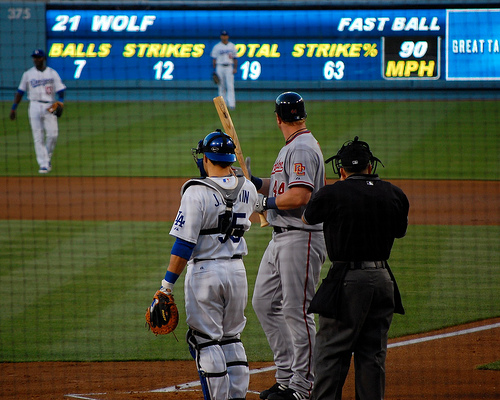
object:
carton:
[144, 278, 179, 336]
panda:
[45, 85, 53, 94]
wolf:
[90, 14, 156, 32]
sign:
[379, 36, 441, 81]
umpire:
[301, 135, 411, 400]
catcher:
[10, 48, 67, 174]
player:
[9, 48, 68, 174]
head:
[220, 30, 229, 42]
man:
[210, 29, 237, 109]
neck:
[221, 40, 229, 44]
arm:
[210, 44, 221, 78]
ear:
[220, 36, 222, 39]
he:
[145, 128, 259, 400]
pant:
[308, 268, 396, 400]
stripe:
[303, 231, 312, 380]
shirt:
[168, 174, 258, 265]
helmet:
[196, 129, 237, 162]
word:
[122, 43, 206, 59]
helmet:
[275, 91, 308, 121]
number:
[399, 41, 429, 59]